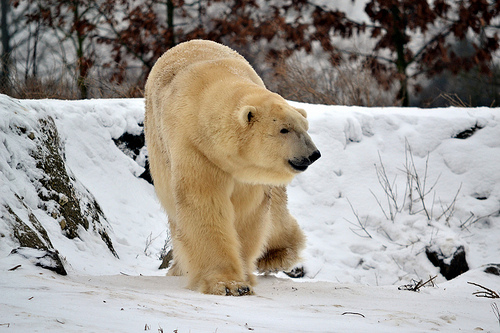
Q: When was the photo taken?
A: Daytime.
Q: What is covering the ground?
A: Snow.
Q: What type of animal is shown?
A: Polar Bear.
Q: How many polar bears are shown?
A: One.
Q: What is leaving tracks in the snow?
A: Bear.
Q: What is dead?
A: Leaves.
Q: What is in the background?
A: Trees.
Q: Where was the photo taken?
A: In the Arctic.